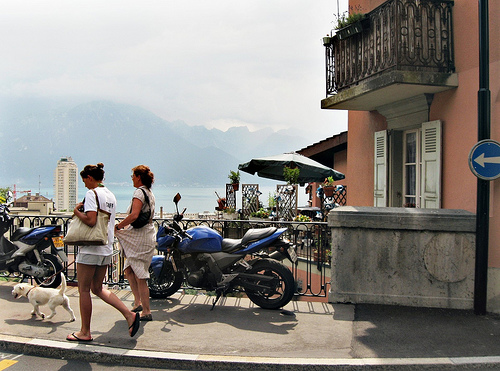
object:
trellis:
[226, 183, 237, 211]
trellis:
[241, 183, 260, 213]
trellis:
[276, 185, 298, 220]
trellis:
[320, 187, 348, 247]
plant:
[225, 169, 240, 189]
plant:
[283, 160, 299, 183]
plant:
[320, 174, 335, 197]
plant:
[255, 208, 270, 225]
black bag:
[127, 186, 152, 228]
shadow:
[3, 314, 77, 335]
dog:
[10, 271, 76, 324]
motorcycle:
[139, 216, 298, 318]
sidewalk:
[0, 277, 497, 364]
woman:
[65, 162, 140, 343]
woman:
[110, 164, 158, 324]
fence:
[154, 220, 334, 297]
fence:
[2, 210, 126, 288]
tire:
[241, 257, 298, 311]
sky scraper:
[54, 155, 79, 213]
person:
[60, 161, 141, 342]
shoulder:
[134, 186, 148, 197]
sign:
[465, 138, 499, 181]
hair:
[80, 162, 107, 182]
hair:
[131, 164, 155, 189]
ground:
[328, 85, 371, 148]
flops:
[64, 310, 145, 342]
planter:
[332, 4, 374, 39]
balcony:
[319, 1, 459, 111]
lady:
[64, 162, 158, 343]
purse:
[62, 188, 112, 246]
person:
[113, 162, 158, 322]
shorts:
[75, 250, 114, 266]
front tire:
[141, 254, 186, 301]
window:
[374, 118, 445, 210]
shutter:
[371, 127, 387, 207]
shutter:
[419, 117, 441, 208]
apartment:
[318, 0, 498, 312]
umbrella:
[237, 150, 346, 200]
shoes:
[130, 314, 153, 322]